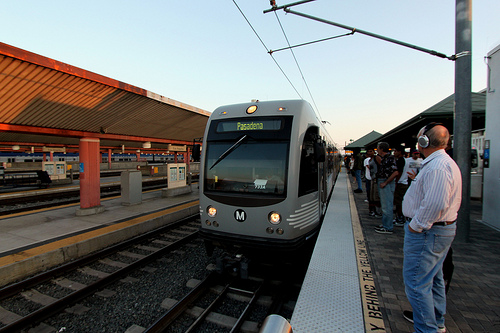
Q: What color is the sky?
A: Blue.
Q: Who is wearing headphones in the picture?
A: The man up front.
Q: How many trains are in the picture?
A: One.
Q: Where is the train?
A: At the train station.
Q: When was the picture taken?
A: During the day.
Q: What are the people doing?
A: Waiting to board the train.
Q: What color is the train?
A: Black and gray.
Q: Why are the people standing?
A: Waiting on the train.